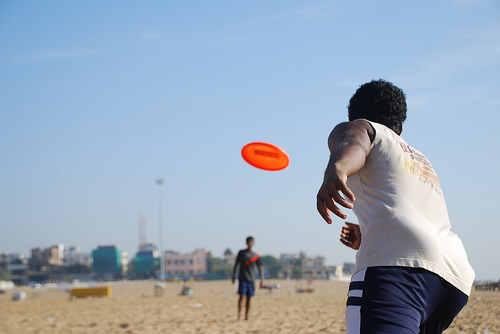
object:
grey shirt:
[236, 249, 265, 283]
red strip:
[242, 253, 259, 270]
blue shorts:
[238, 280, 255, 296]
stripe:
[348, 280, 365, 290]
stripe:
[346, 296, 363, 306]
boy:
[230, 235, 265, 324]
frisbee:
[240, 142, 290, 172]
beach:
[0, 278, 499, 334]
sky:
[0, 0, 499, 278]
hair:
[347, 77, 408, 136]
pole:
[156, 176, 166, 283]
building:
[161, 247, 209, 281]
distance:
[0, 0, 499, 288]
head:
[347, 78, 406, 136]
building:
[0, 243, 89, 289]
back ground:
[0, 0, 499, 334]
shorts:
[344, 264, 470, 333]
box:
[71, 285, 113, 298]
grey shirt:
[349, 117, 475, 297]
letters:
[397, 138, 446, 197]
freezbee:
[241, 141, 290, 171]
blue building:
[91, 244, 124, 283]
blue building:
[127, 241, 162, 281]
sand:
[0, 273, 498, 330]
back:
[346, 77, 408, 134]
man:
[315, 76, 479, 333]